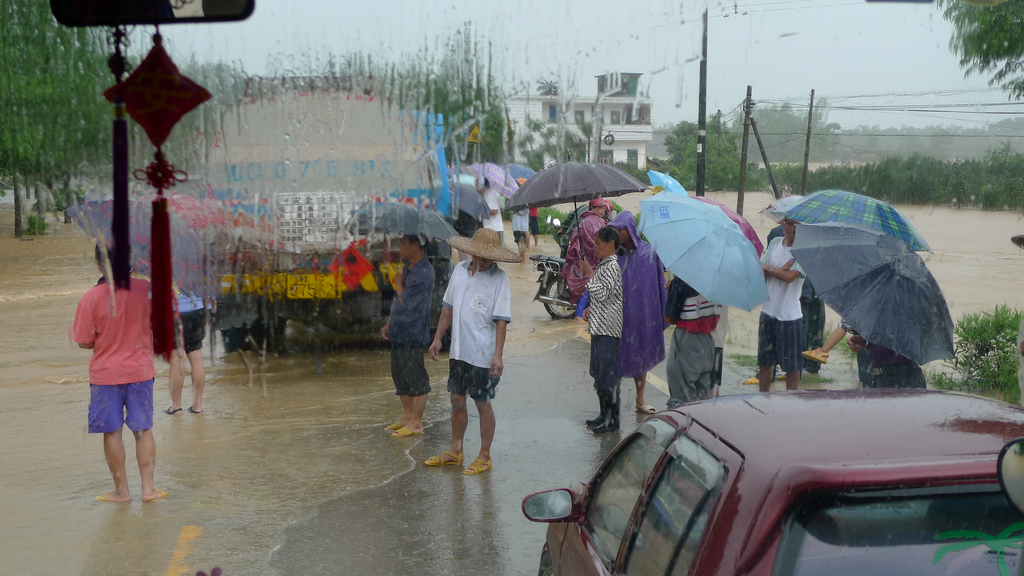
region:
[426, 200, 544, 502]
The man is standing by the edge of flood waters on a street.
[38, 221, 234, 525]
Standing barefoot in the rain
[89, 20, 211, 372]
decorations hanging from the rearview mirror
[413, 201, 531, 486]
a man standing in the rain with a straw hat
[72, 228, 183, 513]
a man standing barefoot in the rain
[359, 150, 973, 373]
a lot of umbrellas in the rain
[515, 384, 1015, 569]
part of a red car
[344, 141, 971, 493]
a crowd of people standing in the rain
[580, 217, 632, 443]
a person in a black and white stripe shirt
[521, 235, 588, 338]
the back of a motorcycle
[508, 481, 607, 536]
side mirror of a car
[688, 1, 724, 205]
telephone pole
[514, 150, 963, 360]
umbrellas protecting against rain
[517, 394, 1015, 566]
car driving in the street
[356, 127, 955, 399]
People standing under umbrellas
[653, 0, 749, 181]
street light pole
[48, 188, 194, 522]
Man holding umbrella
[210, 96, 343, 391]
fountain in the street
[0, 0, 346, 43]
Rear view mirror inside car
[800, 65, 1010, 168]
telephone pole and wire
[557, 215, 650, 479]
Woman under umbrella in the street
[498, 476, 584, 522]
side view mirror on car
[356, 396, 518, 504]
two people wearing yellow shoes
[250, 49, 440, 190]
water running down a windshield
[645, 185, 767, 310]
large light blue umbrella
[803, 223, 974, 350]
large grey-looking umbrella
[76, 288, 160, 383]
man wearing a pink shirt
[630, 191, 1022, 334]
large brownish body of water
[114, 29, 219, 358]
tasseled item hanging from vehicle mirror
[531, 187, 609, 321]
person on a motorbike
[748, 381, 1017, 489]
rain falling on the roof of a red vehicle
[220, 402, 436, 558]
water flooding the street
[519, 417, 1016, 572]
Part of maroon car, showing top, back window, and left side.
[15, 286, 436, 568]
Water is flooding area.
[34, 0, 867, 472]
Scene observed through large windshield.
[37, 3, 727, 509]
Windshield shows rain spatters, rear-view mirror with ornaments on it.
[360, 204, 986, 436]
Numerous pedestrians with umbrellas.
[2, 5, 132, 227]
Green trees in distance, far left.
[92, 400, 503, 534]
Some people with yellow footwear, some with none.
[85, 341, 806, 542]
Many people wearing short and other leg-revealing clothes.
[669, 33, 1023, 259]
Utility lines and poles in distance, far right.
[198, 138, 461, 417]
Blue bus, made barely visible by rain.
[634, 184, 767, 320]
a blue umbrella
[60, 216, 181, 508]
a barefoot person in purple shorts and a pink shirt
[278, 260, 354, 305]
a yellow license plate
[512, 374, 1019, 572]
a burgundy vehicle viewed from the back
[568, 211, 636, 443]
a lady in a black and white striped shirt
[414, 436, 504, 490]
yellow sandals in a puddle of water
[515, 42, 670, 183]
a white building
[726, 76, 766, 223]
a utility pole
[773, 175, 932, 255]
an open plaid umbrella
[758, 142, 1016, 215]
green bushes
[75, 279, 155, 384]
A pink colored shirt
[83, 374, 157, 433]
a bluish pair of shorts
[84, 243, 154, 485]
the back of a man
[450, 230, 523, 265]
a tan straw hat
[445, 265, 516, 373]
a white short sleeved shirt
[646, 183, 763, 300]
a pale blue umbrella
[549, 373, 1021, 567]
a red vehicle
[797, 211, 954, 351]
a gray umbrella that is in use